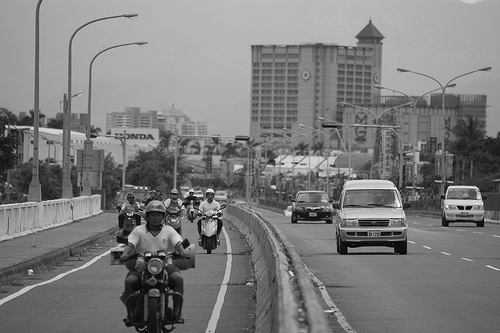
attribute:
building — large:
[247, 15, 386, 160]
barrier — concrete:
[234, 226, 332, 316]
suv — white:
[325, 177, 406, 254]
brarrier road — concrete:
[256, 217, 324, 328]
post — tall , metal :
[61, 10, 140, 195]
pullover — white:
[122, 225, 184, 266]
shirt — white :
[130, 227, 177, 254]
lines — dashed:
[427, 243, 489, 273]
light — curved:
[398, 67, 440, 95]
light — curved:
[441, 62, 490, 86]